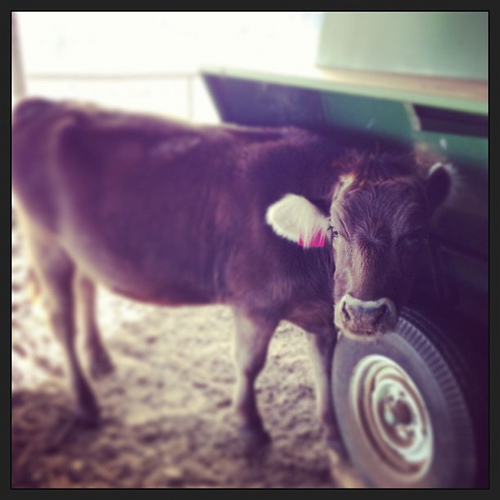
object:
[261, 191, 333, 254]
ear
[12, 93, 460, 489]
cow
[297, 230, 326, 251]
tag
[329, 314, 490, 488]
tire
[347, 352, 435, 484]
metal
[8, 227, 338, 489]
dirt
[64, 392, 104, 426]
hooves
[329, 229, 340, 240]
eye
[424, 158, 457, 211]
ear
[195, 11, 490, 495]
truck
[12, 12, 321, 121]
window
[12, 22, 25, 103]
pane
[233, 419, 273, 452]
hoof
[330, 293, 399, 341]
snout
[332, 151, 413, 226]
hair